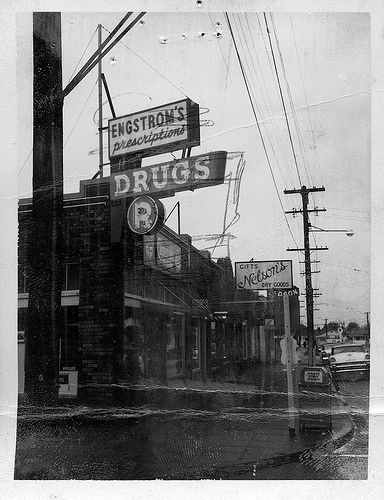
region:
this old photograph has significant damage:
[16, 369, 366, 479]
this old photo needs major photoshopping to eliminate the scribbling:
[90, 88, 249, 293]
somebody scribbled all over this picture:
[89, 83, 251, 300]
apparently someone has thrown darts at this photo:
[92, 0, 239, 61]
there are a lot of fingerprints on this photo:
[11, 417, 367, 482]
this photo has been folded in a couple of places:
[11, 365, 367, 435]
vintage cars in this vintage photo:
[315, 333, 369, 384]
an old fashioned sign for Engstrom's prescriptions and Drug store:
[91, 88, 247, 299]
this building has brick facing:
[15, 171, 119, 410]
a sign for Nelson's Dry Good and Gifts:
[231, 256, 295, 292]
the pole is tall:
[277, 177, 346, 384]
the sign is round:
[122, 193, 164, 236]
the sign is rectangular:
[227, 251, 303, 294]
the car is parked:
[323, 339, 377, 381]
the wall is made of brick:
[86, 295, 117, 357]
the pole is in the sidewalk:
[277, 288, 302, 445]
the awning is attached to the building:
[147, 295, 215, 325]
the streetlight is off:
[339, 222, 358, 243]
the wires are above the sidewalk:
[228, 49, 299, 147]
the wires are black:
[218, 47, 305, 147]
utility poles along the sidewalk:
[27, 17, 321, 391]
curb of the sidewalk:
[203, 407, 358, 490]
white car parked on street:
[326, 341, 369, 377]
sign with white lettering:
[107, 154, 222, 201]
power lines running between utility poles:
[224, 12, 323, 305]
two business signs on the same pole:
[107, 104, 235, 249]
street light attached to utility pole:
[310, 225, 358, 237]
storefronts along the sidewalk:
[87, 209, 297, 394]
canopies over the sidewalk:
[131, 287, 271, 330]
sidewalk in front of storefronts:
[30, 324, 320, 489]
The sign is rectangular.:
[231, 254, 296, 292]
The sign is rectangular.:
[106, 96, 200, 160]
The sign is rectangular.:
[107, 149, 230, 200]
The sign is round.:
[124, 194, 172, 236]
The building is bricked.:
[13, 159, 220, 421]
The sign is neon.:
[101, 149, 231, 199]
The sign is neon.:
[123, 194, 166, 238]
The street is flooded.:
[1, 185, 366, 477]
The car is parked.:
[325, 340, 374, 384]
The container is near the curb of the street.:
[284, 343, 367, 481]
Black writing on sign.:
[105, 104, 213, 150]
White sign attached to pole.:
[91, 116, 234, 159]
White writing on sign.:
[105, 164, 237, 191]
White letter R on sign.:
[120, 200, 205, 216]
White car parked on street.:
[331, 337, 366, 395]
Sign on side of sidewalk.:
[295, 363, 334, 390]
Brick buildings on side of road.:
[75, 264, 258, 367]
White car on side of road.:
[315, 345, 331, 357]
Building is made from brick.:
[62, 244, 207, 335]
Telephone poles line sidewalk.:
[293, 237, 324, 368]